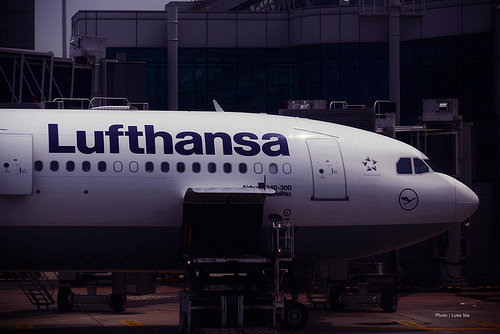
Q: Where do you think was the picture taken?
A: It was taken at the hangar.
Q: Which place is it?
A: It is a hangar.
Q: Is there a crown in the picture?
A: No, there are no crowns.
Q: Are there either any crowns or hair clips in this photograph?
A: No, there are no crowns or hair clips.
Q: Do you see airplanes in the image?
A: Yes, there is an airplane.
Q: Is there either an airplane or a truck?
A: Yes, there is an airplane.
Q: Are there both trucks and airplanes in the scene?
A: No, there is an airplane but no trucks.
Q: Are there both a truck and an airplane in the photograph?
A: No, there is an airplane but no trucks.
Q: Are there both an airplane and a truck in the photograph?
A: No, there is an airplane but no trucks.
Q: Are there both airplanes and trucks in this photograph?
A: No, there is an airplane but no trucks.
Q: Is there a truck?
A: No, there are no trucks.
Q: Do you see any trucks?
A: No, there are no trucks.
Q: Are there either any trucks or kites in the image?
A: No, there are no trucks or kites.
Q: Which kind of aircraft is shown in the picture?
A: The aircraft is an airplane.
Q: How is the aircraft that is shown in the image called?
A: The aircraft is an airplane.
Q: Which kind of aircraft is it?
A: The aircraft is an airplane.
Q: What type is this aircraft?
A: That is an airplane.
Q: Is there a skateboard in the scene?
A: No, there are no skateboards.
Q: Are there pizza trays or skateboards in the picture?
A: No, there are no skateboards or pizza trays.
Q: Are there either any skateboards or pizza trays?
A: No, there are no skateboards or pizza trays.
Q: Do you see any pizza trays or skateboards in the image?
A: No, there are no skateboards or pizza trays.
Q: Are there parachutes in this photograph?
A: No, there are no parachutes.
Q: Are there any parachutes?
A: No, there are no parachutes.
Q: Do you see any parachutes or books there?
A: No, there are no parachutes or books.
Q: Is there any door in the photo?
A: Yes, there is a door.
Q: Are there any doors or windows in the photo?
A: Yes, there is a door.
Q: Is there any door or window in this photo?
A: Yes, there is a door.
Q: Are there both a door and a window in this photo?
A: Yes, there are both a door and a window.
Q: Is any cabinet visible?
A: No, there are no cabinets.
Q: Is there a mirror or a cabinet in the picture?
A: No, there are no cabinets or mirrors.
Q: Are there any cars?
A: No, there are no cars.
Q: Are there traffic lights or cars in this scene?
A: No, there are no cars or traffic lights.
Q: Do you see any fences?
A: No, there are no fences.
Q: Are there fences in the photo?
A: No, there are no fences.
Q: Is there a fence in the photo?
A: No, there are no fences.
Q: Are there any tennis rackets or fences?
A: No, there are no fences or tennis rackets.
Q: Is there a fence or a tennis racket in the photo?
A: No, there are no fences or rackets.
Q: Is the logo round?
A: Yes, the logo is round.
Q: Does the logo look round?
A: Yes, the logo is round.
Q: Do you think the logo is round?
A: Yes, the logo is round.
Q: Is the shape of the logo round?
A: Yes, the logo is round.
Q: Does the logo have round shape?
A: Yes, the logo is round.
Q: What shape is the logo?
A: The logo is round.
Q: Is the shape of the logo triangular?
A: No, the logo is round.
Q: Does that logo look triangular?
A: No, the logo is round.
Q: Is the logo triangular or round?
A: The logo is round.